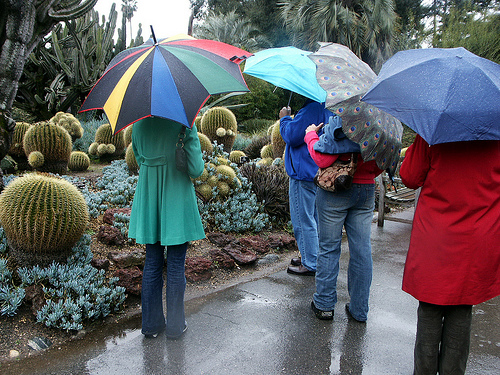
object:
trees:
[187, 0, 397, 120]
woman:
[304, 104, 383, 321]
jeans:
[313, 184, 372, 323]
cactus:
[16, 150, 89, 236]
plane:
[69, 229, 500, 374]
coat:
[127, 117, 207, 245]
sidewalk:
[0, 206, 500, 375]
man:
[278, 99, 335, 276]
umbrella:
[306, 41, 402, 179]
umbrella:
[77, 35, 254, 136]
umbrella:
[242, 42, 330, 109]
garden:
[0, 0, 500, 375]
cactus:
[0, 107, 294, 255]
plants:
[0, 107, 294, 332]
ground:
[0, 163, 500, 375]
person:
[132, 120, 204, 339]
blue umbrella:
[360, 47, 500, 146]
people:
[126, 100, 500, 375]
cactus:
[2, 0, 143, 122]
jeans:
[140, 242, 185, 339]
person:
[399, 134, 500, 375]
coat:
[399, 132, 500, 305]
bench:
[377, 148, 422, 228]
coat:
[279, 99, 333, 181]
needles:
[7, 181, 78, 253]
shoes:
[145, 323, 187, 339]